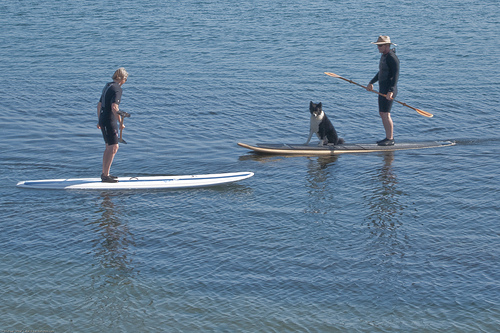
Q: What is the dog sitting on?
A: Paddle board.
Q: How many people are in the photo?
A: Two.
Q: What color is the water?
A: Blue.